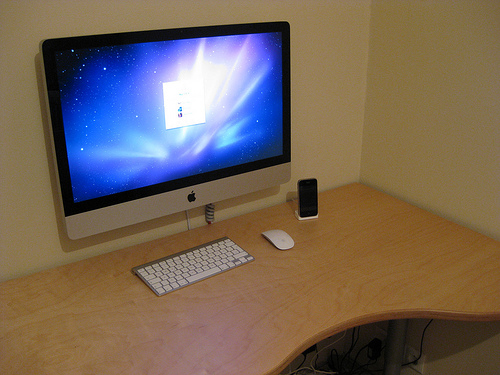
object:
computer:
[37, 21, 291, 241]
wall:
[291, 0, 364, 177]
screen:
[53, 30, 283, 204]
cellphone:
[297, 177, 317, 217]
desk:
[0, 179, 499, 375]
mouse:
[259, 229, 294, 251]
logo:
[186, 190, 197, 203]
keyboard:
[131, 235, 255, 297]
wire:
[184, 210, 191, 231]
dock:
[294, 209, 319, 221]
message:
[161, 75, 206, 130]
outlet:
[403, 347, 427, 375]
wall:
[372, 58, 500, 199]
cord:
[402, 316, 434, 367]